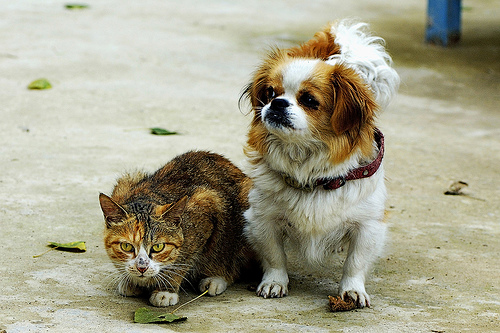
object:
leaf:
[150, 127, 185, 137]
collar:
[274, 124, 384, 192]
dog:
[238, 16, 399, 306]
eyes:
[119, 240, 135, 255]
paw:
[256, 279, 290, 300]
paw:
[201, 273, 228, 296]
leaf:
[327, 293, 357, 313]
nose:
[136, 258, 149, 274]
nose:
[267, 95, 290, 112]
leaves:
[24, 75, 55, 93]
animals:
[97, 149, 265, 304]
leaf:
[134, 307, 188, 324]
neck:
[240, 132, 382, 185]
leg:
[424, 0, 463, 45]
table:
[424, 0, 469, 51]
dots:
[140, 258, 143, 261]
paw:
[333, 284, 372, 309]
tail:
[330, 15, 402, 115]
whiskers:
[160, 268, 191, 285]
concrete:
[0, 0, 499, 333]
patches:
[296, 60, 379, 164]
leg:
[241, 207, 289, 300]